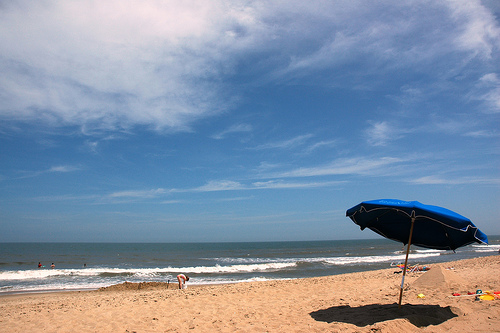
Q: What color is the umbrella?
A: Blue.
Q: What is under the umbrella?
A: A shadow.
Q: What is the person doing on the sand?
A: Building sand castles.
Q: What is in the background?
A: The ocean.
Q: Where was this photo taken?
A: At the beach.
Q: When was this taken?
A: During the daytime.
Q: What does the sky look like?
A: Partly cloudy.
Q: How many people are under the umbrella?
A: None.